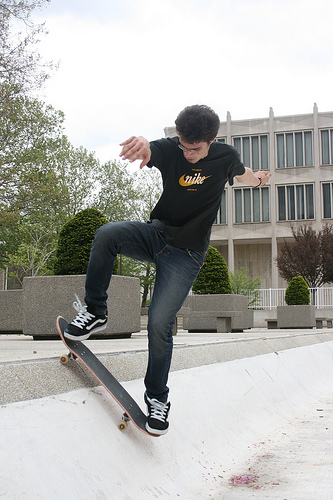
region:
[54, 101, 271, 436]
Man on a skateboard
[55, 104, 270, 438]
Man riding a skateboard on a ramp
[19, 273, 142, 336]
Square concrete plant holders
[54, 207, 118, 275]
Trimmed oval shaped pine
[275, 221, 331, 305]
Tree with burgundy leaves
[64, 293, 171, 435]
Black skater shoes with white laces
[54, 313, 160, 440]
Black skateboard with red rim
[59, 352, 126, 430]
Two yellow skateboard wheels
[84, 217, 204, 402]
Faded dark denim skinny jeans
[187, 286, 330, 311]
White railing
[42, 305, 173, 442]
Black and white skateboard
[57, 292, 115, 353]
Black and white shoe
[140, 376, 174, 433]
Black and white shoe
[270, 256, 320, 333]
Plant growing in concrete block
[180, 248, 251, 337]
Plant growing in concrete block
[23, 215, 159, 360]
Plant growing in concrete block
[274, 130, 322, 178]
Long windows on a building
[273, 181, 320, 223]
Long windows on a building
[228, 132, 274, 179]
Long windows on a building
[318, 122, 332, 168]
Long windows on a building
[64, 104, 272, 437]
Man riding black skateboard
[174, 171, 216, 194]
Nike logo on black shirt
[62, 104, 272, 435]
Man wearing blue jeans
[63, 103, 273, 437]
Man wearing black shirt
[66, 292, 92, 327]
White shoelace on black shoe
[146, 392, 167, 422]
White shoelace on black shoe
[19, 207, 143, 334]
Large bush planter behind man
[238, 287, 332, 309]
White fence on building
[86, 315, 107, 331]
White stripe on black shoe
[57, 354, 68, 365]
Small wheel on skateboard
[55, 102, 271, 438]
Boy on a skateboard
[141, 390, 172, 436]
Black shoe with white laces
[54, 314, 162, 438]
Black skateboard with orange trim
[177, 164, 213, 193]
Yellow and gold Nike advertisement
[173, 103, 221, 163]
Man wearing glasses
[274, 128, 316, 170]
Four windows on front of building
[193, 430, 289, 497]
Pink debris on the ground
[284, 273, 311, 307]
Dark green bush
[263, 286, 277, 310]
White metal fence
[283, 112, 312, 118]
Top edge of a building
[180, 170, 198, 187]
The white letter N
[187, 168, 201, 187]
the white letter I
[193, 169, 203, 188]
the white letter K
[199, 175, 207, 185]
the white letter E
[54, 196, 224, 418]
these are blue jeans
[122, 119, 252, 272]
this is a tshirt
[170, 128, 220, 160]
these are eye glasses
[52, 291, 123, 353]
this is a shoe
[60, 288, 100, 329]
these are shoe laces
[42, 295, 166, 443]
this is a skateboard